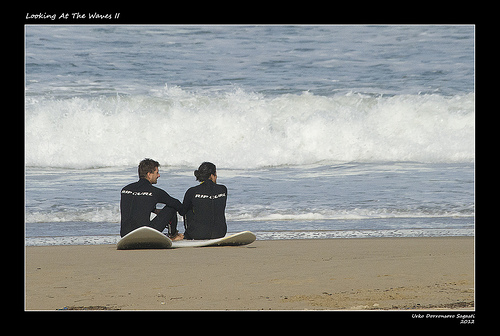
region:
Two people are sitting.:
[110, 148, 277, 263]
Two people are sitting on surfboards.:
[87, 147, 271, 254]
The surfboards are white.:
[114, 208, 268, 265]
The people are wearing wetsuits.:
[118, 152, 239, 254]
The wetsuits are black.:
[112, 152, 253, 244]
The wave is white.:
[222, 104, 393, 151]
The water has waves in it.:
[249, 90, 441, 165]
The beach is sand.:
[276, 245, 464, 307]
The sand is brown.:
[277, 247, 474, 310]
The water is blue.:
[297, 34, 437, 79]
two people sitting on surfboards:
[98, 135, 283, 262]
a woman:
[178, 158, 236, 243]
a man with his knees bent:
[109, 151, 184, 247]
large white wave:
[23, 83, 478, 164]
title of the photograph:
[23, 5, 128, 23]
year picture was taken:
[455, 318, 480, 327]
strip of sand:
[28, 243, 473, 305]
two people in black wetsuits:
[99, 152, 261, 254]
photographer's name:
[406, 310, 480, 320]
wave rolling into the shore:
[24, 202, 472, 220]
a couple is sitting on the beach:
[110, 155, 231, 249]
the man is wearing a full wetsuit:
[122, 180, 182, 240]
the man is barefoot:
[171, 229, 191, 246]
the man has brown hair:
[138, 155, 159, 183]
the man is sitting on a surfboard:
[116, 154, 178, 254]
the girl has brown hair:
[188, 160, 216, 185]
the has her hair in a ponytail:
[193, 160, 219, 186]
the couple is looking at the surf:
[105, 80, 475, 186]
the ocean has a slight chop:
[30, 25, 472, 85]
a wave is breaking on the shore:
[29, 76, 474, 253]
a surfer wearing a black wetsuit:
[120, 158, 182, 240]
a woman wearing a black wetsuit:
[182, 162, 227, 239]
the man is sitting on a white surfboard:
[117, 226, 174, 248]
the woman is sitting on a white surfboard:
[171, 230, 256, 246]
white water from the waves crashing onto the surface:
[26, 81, 476, 163]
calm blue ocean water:
[25, 25, 474, 89]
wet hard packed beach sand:
[26, 247, 474, 310]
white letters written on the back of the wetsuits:
[195, 192, 225, 199]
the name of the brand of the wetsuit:
[120, 188, 154, 198]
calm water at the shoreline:
[258, 166, 475, 236]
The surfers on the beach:
[113, 151, 257, 252]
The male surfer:
[113, 150, 183, 240]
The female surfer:
[177, 155, 229, 240]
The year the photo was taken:
[456, 317, 478, 326]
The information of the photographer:
[409, 309, 476, 321]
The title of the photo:
[21, 8, 122, 23]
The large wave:
[28, 75, 475, 172]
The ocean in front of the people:
[24, 25, 473, 241]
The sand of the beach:
[21, 235, 473, 310]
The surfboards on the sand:
[113, 225, 258, 246]